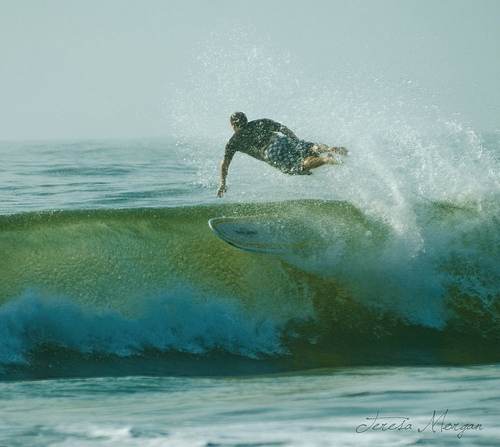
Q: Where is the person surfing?
A: The ocean.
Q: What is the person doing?
A: Surfing.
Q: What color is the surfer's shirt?
A: Black.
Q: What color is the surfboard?
A: White.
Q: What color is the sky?
A: Blue.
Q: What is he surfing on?
A: Water.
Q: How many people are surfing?
A: 1.